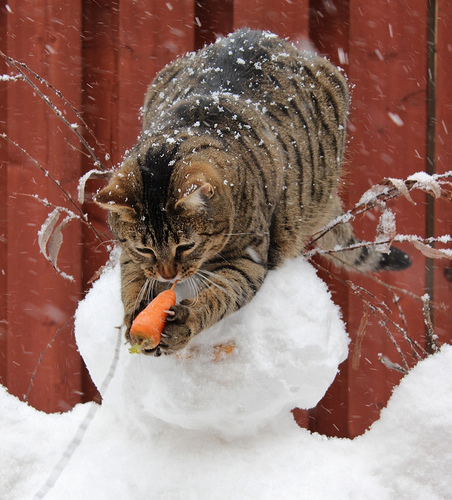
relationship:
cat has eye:
[88, 27, 412, 360] [176, 241, 198, 262]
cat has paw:
[88, 27, 412, 360] [159, 298, 198, 359]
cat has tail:
[88, 27, 412, 360] [309, 194, 410, 273]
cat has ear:
[88, 27, 412, 360] [169, 187, 210, 219]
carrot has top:
[126, 285, 184, 357] [126, 331, 156, 357]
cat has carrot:
[88, 27, 412, 360] [126, 285, 184, 357]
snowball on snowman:
[70, 247, 350, 438] [2, 240, 451, 498]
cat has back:
[88, 27, 412, 360] [137, 28, 316, 140]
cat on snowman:
[88, 27, 412, 360] [2, 240, 451, 498]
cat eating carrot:
[88, 27, 412, 360] [126, 285, 184, 357]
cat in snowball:
[88, 27, 412, 360] [70, 247, 350, 438]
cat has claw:
[88, 27, 412, 360] [159, 308, 178, 319]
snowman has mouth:
[2, 240, 451, 498] [169, 337, 242, 363]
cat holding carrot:
[88, 27, 412, 360] [126, 285, 184, 357]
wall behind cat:
[1, 4, 451, 438] [88, 27, 412, 360]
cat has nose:
[88, 27, 412, 360] [162, 267, 180, 282]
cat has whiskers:
[88, 27, 412, 360] [189, 267, 250, 314]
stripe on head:
[138, 151, 171, 247] [107, 141, 232, 281]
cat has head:
[88, 27, 412, 360] [107, 141, 232, 281]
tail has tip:
[309, 194, 410, 273] [373, 247, 416, 272]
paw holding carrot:
[159, 298, 198, 359] [126, 285, 184, 357]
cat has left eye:
[88, 27, 412, 360] [136, 243, 154, 255]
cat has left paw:
[88, 27, 412, 360] [122, 301, 148, 334]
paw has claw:
[159, 298, 198, 359] [159, 308, 178, 319]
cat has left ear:
[88, 27, 412, 360] [94, 185, 139, 214]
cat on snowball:
[88, 27, 412, 360] [70, 247, 350, 438]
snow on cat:
[163, 132, 178, 150] [88, 27, 412, 360]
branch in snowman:
[301, 236, 451, 264] [2, 240, 451, 498]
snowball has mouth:
[70, 247, 350, 438] [169, 337, 242, 363]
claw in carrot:
[159, 308, 178, 319] [126, 285, 184, 357]